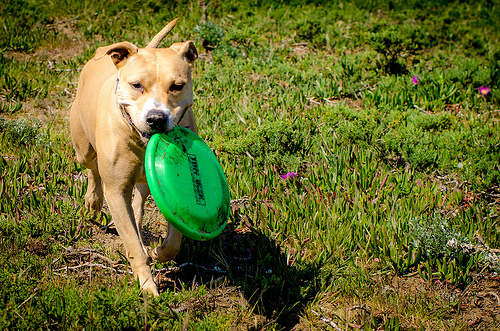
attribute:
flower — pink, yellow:
[474, 85, 484, 99]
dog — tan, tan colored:
[65, 15, 199, 305]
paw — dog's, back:
[82, 187, 106, 214]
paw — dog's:
[144, 236, 184, 262]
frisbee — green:
[144, 126, 233, 241]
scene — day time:
[3, 2, 484, 328]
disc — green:
[142, 123, 233, 242]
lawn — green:
[2, 0, 484, 328]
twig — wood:
[50, 247, 136, 280]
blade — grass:
[314, 228, 333, 258]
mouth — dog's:
[117, 103, 193, 153]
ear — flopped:
[90, 39, 140, 70]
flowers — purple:
[408, 70, 484, 97]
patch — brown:
[19, 16, 96, 60]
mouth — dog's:
[118, 103, 193, 148]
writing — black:
[184, 147, 209, 206]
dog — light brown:
[62, 13, 222, 312]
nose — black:
[141, 111, 173, 135]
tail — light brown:
[137, 12, 183, 44]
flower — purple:
[407, 69, 421, 88]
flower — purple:
[479, 81, 491, 102]